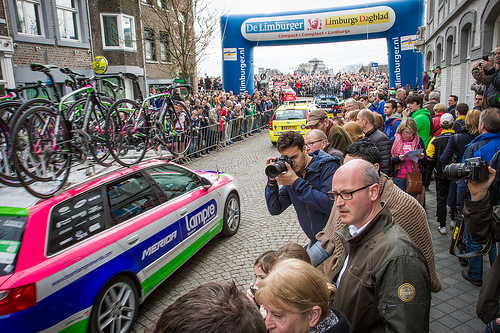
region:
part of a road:
[243, 233, 254, 241]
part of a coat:
[375, 275, 410, 325]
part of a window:
[94, 187, 143, 251]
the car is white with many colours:
[8, 106, 241, 322]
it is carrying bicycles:
[6, 20, 233, 230]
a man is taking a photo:
[233, 120, 303, 205]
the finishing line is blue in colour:
[233, 8, 343, 43]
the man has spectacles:
[320, 153, 384, 218]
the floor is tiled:
[212, 140, 257, 162]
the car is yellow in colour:
[269, 111, 303, 131]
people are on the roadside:
[148, 75, 248, 118]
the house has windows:
[73, 0, 195, 72]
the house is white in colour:
[424, 10, 488, 59]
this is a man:
[331, 162, 426, 325]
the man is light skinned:
[353, 196, 370, 218]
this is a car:
[73, 182, 220, 264]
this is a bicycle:
[110, 89, 210, 146]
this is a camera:
[266, 151, 288, 176]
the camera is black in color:
[265, 156, 280, 169]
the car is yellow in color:
[276, 122, 293, 129]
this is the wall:
[22, 13, 157, 45]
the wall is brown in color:
[137, 7, 167, 27]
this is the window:
[101, 15, 118, 45]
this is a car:
[110, 163, 224, 261]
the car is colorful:
[110, 167, 226, 252]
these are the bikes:
[9, 75, 175, 170]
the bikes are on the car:
[1, 60, 181, 170]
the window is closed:
[156, 163, 188, 190]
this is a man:
[325, 152, 396, 275]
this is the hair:
[273, 263, 319, 306]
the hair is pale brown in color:
[271, 258, 326, 301]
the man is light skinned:
[339, 166, 361, 180]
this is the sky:
[265, 46, 286, 61]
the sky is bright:
[326, 43, 351, 54]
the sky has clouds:
[331, 45, 344, 58]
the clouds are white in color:
[329, 45, 346, 62]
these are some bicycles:
[6, 49, 196, 175]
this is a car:
[2, 154, 240, 327]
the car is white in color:
[143, 229, 153, 237]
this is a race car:
[273, 93, 344, 139]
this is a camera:
[269, 157, 290, 180]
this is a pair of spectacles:
[326, 181, 368, 205]